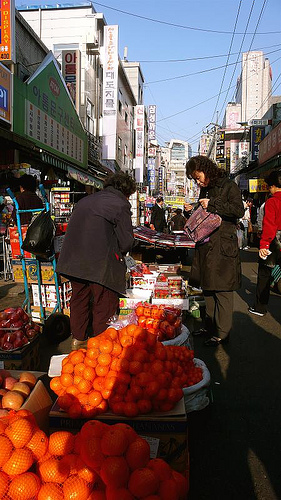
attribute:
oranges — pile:
[42, 321, 208, 424]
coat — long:
[182, 166, 251, 298]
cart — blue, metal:
[2, 181, 75, 345]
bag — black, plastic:
[20, 204, 64, 264]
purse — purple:
[179, 199, 226, 248]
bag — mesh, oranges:
[1, 405, 199, 497]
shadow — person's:
[215, 308, 278, 498]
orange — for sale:
[76, 379, 92, 393]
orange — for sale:
[92, 373, 106, 388]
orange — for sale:
[97, 338, 113, 353]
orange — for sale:
[47, 375, 65, 390]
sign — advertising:
[11, 50, 89, 170]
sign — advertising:
[61, 48, 80, 118]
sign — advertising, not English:
[100, 23, 117, 160]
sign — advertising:
[133, 104, 144, 183]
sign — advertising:
[237, 141, 249, 168]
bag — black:
[18, 208, 53, 259]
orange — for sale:
[98, 427, 127, 456]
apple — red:
[16, 370, 35, 387]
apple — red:
[10, 380, 30, 397]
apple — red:
[1, 390, 23, 411]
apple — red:
[2, 375, 17, 389]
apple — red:
[1, 368, 12, 378]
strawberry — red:
[154, 288, 158, 292]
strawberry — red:
[157, 289, 162, 293]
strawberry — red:
[155, 291, 163, 297]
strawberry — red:
[171, 292, 175, 296]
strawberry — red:
[162, 289, 167, 295]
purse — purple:
[182, 205, 222, 243]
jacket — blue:
[53, 185, 135, 297]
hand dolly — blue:
[4, 182, 61, 325]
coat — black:
[187, 173, 245, 292]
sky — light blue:
[13, 0, 279, 155]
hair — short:
[100, 168, 139, 194]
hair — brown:
[96, 167, 141, 200]